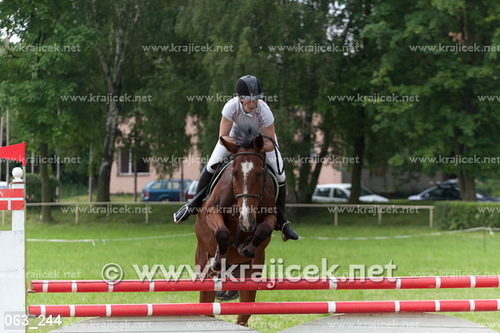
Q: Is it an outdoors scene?
A: Yes, it is outdoors.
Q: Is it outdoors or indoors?
A: It is outdoors.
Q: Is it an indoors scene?
A: No, it is outdoors.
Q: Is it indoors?
A: No, it is outdoors.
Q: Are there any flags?
A: Yes, there is a flag.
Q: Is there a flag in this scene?
A: Yes, there is a flag.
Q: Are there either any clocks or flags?
A: Yes, there is a flag.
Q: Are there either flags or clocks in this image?
A: Yes, there is a flag.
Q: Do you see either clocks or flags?
A: Yes, there is a flag.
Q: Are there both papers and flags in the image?
A: No, there is a flag but no papers.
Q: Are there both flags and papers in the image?
A: No, there is a flag but no papers.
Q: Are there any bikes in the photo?
A: No, there are no bikes.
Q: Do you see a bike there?
A: No, there are no bikes.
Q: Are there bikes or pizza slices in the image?
A: No, there are no bikes or pizza slices.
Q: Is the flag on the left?
A: Yes, the flag is on the left of the image.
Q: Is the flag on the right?
A: No, the flag is on the left of the image.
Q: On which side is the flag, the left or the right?
A: The flag is on the left of the image.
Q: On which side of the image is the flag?
A: The flag is on the left of the image.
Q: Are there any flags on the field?
A: Yes, there is a flag on the field.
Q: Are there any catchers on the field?
A: No, there is a flag on the field.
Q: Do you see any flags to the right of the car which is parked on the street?
A: No, the flag is to the left of the car.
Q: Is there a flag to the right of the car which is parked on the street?
A: No, the flag is to the left of the car.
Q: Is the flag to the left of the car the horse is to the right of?
A: Yes, the flag is to the left of the car.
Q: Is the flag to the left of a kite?
A: No, the flag is to the left of the car.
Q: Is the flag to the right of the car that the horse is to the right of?
A: No, the flag is to the left of the car.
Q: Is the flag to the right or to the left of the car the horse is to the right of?
A: The flag is to the left of the car.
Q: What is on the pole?
A: The flag is on the pole.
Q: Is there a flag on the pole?
A: Yes, there is a flag on the pole.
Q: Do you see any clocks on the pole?
A: No, there is a flag on the pole.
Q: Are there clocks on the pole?
A: No, there is a flag on the pole.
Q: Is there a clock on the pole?
A: No, there is a flag on the pole.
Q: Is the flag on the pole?
A: Yes, the flag is on the pole.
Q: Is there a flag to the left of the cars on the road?
A: Yes, there is a flag to the left of the cars.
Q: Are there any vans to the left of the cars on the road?
A: No, there is a flag to the left of the cars.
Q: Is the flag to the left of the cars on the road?
A: Yes, the flag is to the left of the cars.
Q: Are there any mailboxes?
A: No, there are no mailboxes.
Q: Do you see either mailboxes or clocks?
A: No, there are no mailboxes or clocks.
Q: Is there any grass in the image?
A: Yes, there is grass.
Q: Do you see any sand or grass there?
A: Yes, there is grass.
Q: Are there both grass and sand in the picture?
A: No, there is grass but no sand.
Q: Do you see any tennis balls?
A: No, there are no tennis balls.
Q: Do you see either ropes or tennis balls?
A: No, there are no tennis balls or ropes.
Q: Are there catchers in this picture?
A: No, there are no catchers.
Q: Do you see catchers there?
A: No, there are no catchers.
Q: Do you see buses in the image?
A: No, there are no buses.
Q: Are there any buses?
A: No, there are no buses.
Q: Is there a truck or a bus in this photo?
A: No, there are no buses or trucks.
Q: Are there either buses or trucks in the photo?
A: No, there are no buses or trucks.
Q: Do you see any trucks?
A: No, there are no trucks.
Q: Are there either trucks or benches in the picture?
A: No, there are no trucks or benches.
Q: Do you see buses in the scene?
A: No, there are no buses.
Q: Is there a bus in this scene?
A: No, there are no buses.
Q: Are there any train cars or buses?
A: No, there are no buses or train cars.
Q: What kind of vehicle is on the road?
A: The vehicles are cars.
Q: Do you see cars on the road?
A: Yes, there are cars on the road.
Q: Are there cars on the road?
A: Yes, there are cars on the road.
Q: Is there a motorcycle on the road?
A: No, there are cars on the road.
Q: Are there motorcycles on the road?
A: No, there are cars on the road.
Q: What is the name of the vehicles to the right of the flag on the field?
A: The vehicles are cars.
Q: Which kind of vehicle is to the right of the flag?
A: The vehicles are cars.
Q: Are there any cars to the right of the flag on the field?
A: Yes, there are cars to the right of the flag.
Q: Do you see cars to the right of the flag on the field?
A: Yes, there are cars to the right of the flag.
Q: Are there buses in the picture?
A: No, there are no buses.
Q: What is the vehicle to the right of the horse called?
A: The vehicle is a car.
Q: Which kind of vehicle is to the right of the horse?
A: The vehicle is a car.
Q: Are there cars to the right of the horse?
A: Yes, there is a car to the right of the horse.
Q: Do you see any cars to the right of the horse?
A: Yes, there is a car to the right of the horse.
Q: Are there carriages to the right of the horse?
A: No, there is a car to the right of the horse.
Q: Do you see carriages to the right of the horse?
A: No, there is a car to the right of the horse.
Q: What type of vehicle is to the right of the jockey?
A: The vehicle is a car.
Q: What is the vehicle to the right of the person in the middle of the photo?
A: The vehicle is a car.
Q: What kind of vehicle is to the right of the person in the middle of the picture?
A: The vehicle is a car.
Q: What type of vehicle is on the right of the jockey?
A: The vehicle is a car.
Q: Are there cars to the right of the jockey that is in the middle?
A: Yes, there is a car to the right of the jockey.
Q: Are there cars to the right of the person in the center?
A: Yes, there is a car to the right of the jockey.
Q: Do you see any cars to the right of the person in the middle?
A: Yes, there is a car to the right of the jockey.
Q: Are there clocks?
A: No, there are no clocks.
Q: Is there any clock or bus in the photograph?
A: No, there are no clocks or buses.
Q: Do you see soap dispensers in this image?
A: No, there are no soap dispensers.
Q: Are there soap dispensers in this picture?
A: No, there are no soap dispensers.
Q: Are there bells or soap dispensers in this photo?
A: No, there are no soap dispensers or bells.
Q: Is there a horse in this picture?
A: Yes, there is a horse.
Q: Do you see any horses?
A: Yes, there is a horse.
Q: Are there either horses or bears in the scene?
A: Yes, there is a horse.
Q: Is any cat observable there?
A: No, there are no cats.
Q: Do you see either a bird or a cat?
A: No, there are no cats or birds.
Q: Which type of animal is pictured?
A: The animal is a horse.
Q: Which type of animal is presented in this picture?
A: The animal is a horse.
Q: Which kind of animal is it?
A: The animal is a horse.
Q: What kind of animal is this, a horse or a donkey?
A: This is a horse.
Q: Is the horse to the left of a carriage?
A: No, the horse is to the left of a car.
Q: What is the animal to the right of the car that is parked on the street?
A: The animal is a horse.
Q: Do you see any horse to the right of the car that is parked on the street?
A: Yes, there is a horse to the right of the car.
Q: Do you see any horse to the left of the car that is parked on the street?
A: No, the horse is to the right of the car.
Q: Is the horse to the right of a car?
A: Yes, the horse is to the right of a car.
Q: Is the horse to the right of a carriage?
A: No, the horse is to the right of a car.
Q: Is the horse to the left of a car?
A: No, the horse is to the right of a car.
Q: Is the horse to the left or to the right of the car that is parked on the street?
A: The horse is to the right of the car.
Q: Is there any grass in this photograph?
A: Yes, there is grass.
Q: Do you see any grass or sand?
A: Yes, there is grass.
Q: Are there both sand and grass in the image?
A: No, there is grass but no sand.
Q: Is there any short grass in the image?
A: Yes, there is short grass.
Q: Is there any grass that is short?
A: Yes, there is grass that is short.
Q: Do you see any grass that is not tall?
A: Yes, there is short grass.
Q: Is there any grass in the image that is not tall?
A: Yes, there is short grass.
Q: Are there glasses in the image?
A: No, there are no glasses.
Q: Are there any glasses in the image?
A: No, there are no glasses.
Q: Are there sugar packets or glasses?
A: No, there are no glasses or sugar packets.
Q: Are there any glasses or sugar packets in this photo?
A: No, there are no glasses or sugar packets.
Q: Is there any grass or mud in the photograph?
A: Yes, there is grass.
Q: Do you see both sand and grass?
A: No, there is grass but no sand.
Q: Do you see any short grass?
A: Yes, there is short grass.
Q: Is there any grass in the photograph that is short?
A: Yes, there is grass that is short.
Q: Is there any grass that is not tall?
A: Yes, there is short grass.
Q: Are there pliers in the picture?
A: No, there are no pliers.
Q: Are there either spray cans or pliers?
A: No, there are no pliers or spray cans.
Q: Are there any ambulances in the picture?
A: No, there are no ambulances.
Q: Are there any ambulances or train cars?
A: No, there are no ambulances or train cars.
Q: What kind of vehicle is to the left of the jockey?
A: The vehicle is a car.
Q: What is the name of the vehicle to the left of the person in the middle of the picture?
A: The vehicle is a car.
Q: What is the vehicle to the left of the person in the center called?
A: The vehicle is a car.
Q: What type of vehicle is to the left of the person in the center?
A: The vehicle is a car.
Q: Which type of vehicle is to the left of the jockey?
A: The vehicle is a car.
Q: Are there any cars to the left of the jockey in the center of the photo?
A: Yes, there is a car to the left of the jockey.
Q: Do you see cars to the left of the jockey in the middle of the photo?
A: Yes, there is a car to the left of the jockey.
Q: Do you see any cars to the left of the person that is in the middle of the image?
A: Yes, there is a car to the left of the jockey.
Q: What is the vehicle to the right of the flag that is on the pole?
A: The vehicle is a car.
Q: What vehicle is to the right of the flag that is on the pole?
A: The vehicle is a car.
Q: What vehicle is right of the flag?
A: The vehicle is a car.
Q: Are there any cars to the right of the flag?
A: Yes, there is a car to the right of the flag.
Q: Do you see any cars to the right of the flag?
A: Yes, there is a car to the right of the flag.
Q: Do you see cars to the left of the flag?
A: No, the car is to the right of the flag.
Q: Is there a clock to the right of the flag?
A: No, there is a car to the right of the flag.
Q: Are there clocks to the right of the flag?
A: No, there is a car to the right of the flag.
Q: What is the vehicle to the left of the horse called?
A: The vehicle is a car.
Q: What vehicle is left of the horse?
A: The vehicle is a car.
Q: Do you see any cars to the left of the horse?
A: Yes, there is a car to the left of the horse.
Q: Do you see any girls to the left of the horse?
A: No, there is a car to the left of the horse.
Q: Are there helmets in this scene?
A: Yes, there is a helmet.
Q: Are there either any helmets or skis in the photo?
A: Yes, there is a helmet.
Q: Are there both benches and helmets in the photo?
A: No, there is a helmet but no benches.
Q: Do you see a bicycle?
A: No, there are no bicycles.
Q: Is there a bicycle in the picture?
A: No, there are no bicycles.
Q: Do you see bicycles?
A: No, there are no bicycles.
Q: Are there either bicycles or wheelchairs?
A: No, there are no bicycles or wheelchairs.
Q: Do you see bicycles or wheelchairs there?
A: No, there are no bicycles or wheelchairs.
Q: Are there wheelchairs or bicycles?
A: No, there are no bicycles or wheelchairs.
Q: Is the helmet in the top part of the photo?
A: Yes, the helmet is in the top of the image.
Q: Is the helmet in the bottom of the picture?
A: No, the helmet is in the top of the image.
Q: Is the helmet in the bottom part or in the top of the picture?
A: The helmet is in the top of the image.